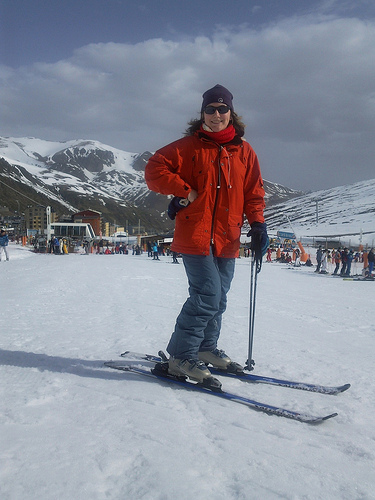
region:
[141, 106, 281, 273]
woman's jacket is red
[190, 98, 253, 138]
woman is wearing sunglasses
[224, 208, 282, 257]
woman's gloves are black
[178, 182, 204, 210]
woman's hand in pocket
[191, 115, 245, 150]
woman wearing red scarf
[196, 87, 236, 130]
the woman is smiling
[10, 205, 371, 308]
people walking behind woman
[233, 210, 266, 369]
woman is holding ski poles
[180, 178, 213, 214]
glove is off right hand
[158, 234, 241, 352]
woman's pants are gray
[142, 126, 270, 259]
A RED SKI JACKET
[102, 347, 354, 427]
A PAIR OF SKIS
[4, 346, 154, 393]
A SHADOW ON THE SNOW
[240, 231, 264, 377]
A PAIR OF SKI POLES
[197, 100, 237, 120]
A PAIR OF SUNGLASSES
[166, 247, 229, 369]
SNOW PANTS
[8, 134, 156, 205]
SNOW COVERED MOUNTAINS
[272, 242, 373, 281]
PEOPLE IN THE BACKGROUND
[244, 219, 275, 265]
A SKI GLOVE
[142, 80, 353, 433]
A WOMAN POSING ON SKIS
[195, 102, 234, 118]
pair of black sun glasses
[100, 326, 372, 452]
pair of blue skis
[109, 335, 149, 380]
skis covered in snow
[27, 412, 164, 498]
ground covered in snow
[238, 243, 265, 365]
two black metal ski poles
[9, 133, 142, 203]
mountainside covered in snow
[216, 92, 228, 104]
design on front of hat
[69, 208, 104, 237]
large building with brown siding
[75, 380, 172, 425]
ski tracks in snow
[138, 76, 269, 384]
woman in orange jacket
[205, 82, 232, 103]
hat on woman's head.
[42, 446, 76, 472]
snow on the ground.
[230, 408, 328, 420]
ski on woman's foot.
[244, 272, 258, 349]
ski poles in woman's hand.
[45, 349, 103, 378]
shadow on the ground.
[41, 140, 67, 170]
snow on the mountains.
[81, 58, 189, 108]
clouds in the sky.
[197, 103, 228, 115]
sunglasses on woman's face.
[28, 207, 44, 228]
building in the background.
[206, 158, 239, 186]
red coat on the woman.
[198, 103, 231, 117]
Woman wearing sunglasses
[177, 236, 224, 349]
Woman in gray pants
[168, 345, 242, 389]
Gray boots on skis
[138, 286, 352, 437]
Woman on skis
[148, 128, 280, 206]
Woman wearing a read jacket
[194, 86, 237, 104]
Woman with a blue hat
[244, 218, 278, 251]
Woman wearing blue gloves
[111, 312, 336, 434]
Skis on a ski slope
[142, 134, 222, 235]
Woman with hand in pocket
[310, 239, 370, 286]
Group skiing